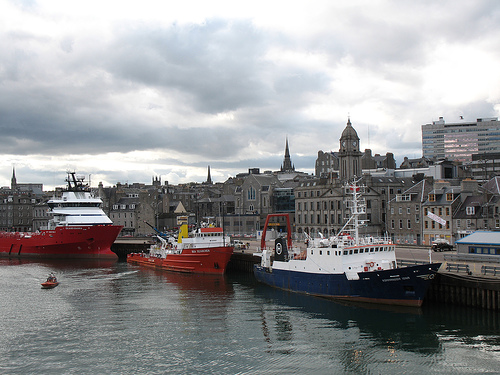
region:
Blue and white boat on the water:
[240, 191, 440, 333]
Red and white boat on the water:
[122, 187, 237, 299]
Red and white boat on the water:
[0, 150, 125, 266]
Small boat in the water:
[18, 258, 74, 302]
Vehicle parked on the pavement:
[422, 231, 458, 252]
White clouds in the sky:
[10, 8, 496, 163]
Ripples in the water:
[4, 251, 400, 374]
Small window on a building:
[396, 215, 406, 234]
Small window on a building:
[401, 213, 413, 230]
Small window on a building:
[386, 215, 396, 230]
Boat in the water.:
[249, 183, 445, 316]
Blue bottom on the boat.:
[249, 180, 444, 318]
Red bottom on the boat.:
[122, 223, 232, 283]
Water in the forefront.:
[2, 248, 495, 370]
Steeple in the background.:
[272, 132, 300, 172]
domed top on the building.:
[332, 115, 365, 142]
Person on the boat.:
[40, 271, 59, 290]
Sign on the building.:
[424, 200, 449, 228]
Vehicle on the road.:
[428, 233, 454, 254]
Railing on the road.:
[442, 258, 470, 276]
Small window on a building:
[293, 201, 304, 213]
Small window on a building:
[300, 198, 310, 216]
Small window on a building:
[312, 196, 321, 213]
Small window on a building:
[421, 205, 428, 216]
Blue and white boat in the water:
[253, 194, 429, 329]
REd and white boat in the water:
[119, 186, 242, 284]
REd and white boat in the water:
[1, 166, 125, 269]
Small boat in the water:
[35, 260, 65, 298]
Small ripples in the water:
[3, 256, 495, 373]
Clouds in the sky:
[6, 5, 493, 182]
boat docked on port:
[249, 206, 471, 342]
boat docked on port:
[116, 198, 244, 294]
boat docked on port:
[0, 166, 132, 299]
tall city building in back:
[2, 167, 65, 237]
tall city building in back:
[379, 170, 496, 255]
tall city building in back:
[297, 171, 362, 236]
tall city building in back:
[231, 166, 289, 228]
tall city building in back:
[277, 124, 297, 182]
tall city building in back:
[331, 107, 367, 183]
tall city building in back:
[419, 104, 499, 154]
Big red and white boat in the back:
[4, 171, 135, 258]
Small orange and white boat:
[121, 204, 246, 275]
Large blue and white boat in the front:
[248, 168, 448, 337]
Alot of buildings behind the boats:
[2, 104, 498, 261]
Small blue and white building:
[429, 206, 499, 275]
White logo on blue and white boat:
[272, 238, 294, 260]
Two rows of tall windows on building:
[289, 197, 364, 244]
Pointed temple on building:
[324, 113, 369, 163]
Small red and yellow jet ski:
[37, 263, 62, 300]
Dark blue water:
[1, 238, 499, 374]